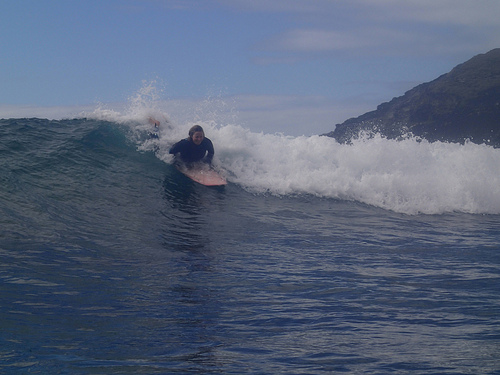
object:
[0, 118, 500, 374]
water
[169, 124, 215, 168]
surfer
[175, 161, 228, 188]
surfboard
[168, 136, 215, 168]
wetsuit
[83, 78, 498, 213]
wave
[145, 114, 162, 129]
feet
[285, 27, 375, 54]
cloud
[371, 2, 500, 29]
cloud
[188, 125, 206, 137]
hair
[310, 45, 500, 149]
hill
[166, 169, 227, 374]
reflection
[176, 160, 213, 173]
hands